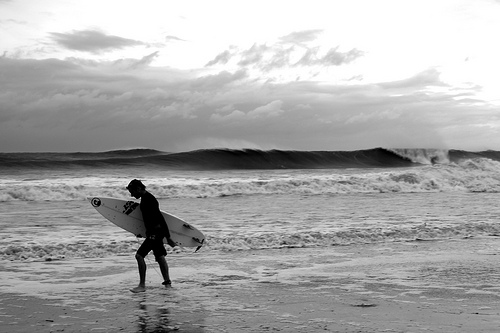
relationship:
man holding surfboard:
[126, 177, 181, 295] [90, 195, 210, 254]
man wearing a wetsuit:
[126, 177, 181, 295] [133, 198, 171, 259]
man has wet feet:
[126, 177, 181, 295] [128, 278, 175, 296]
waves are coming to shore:
[217, 153, 490, 239] [244, 258, 499, 315]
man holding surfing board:
[126, 177, 181, 295] [90, 195, 210, 254]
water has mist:
[0, 144, 498, 330] [266, 85, 469, 133]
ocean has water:
[217, 153, 490, 239] [0, 144, 498, 330]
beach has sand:
[244, 258, 499, 315] [266, 292, 302, 326]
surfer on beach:
[126, 177, 181, 295] [245, 230, 484, 329]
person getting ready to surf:
[126, 177, 181, 295] [221, 157, 436, 246]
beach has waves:
[245, 230, 484, 329] [217, 153, 490, 239]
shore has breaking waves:
[244, 258, 499, 315] [217, 153, 490, 239]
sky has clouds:
[216, 8, 472, 131] [46, 26, 378, 140]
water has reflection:
[128, 297, 224, 330] [126, 301, 183, 330]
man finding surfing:
[126, 177, 181, 295] [111, 159, 275, 297]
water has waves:
[0, 144, 498, 330] [217, 153, 490, 239]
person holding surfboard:
[126, 177, 181, 295] [90, 195, 210, 254]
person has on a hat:
[126, 177, 181, 295] [124, 181, 143, 191]